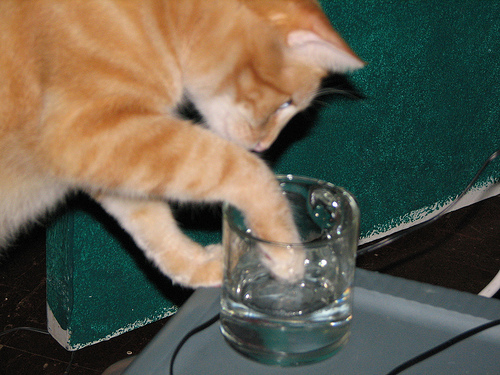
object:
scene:
[0, 0, 500, 375]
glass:
[218, 174, 361, 368]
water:
[221, 270, 351, 354]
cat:
[0, 0, 368, 290]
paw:
[259, 239, 308, 284]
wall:
[72, 0, 499, 350]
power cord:
[476, 268, 500, 299]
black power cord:
[355, 149, 499, 259]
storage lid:
[119, 246, 499, 375]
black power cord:
[381, 319, 499, 375]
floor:
[355, 191, 500, 300]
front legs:
[84, 188, 240, 289]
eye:
[278, 97, 293, 109]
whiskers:
[310, 87, 361, 98]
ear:
[284, 28, 368, 74]